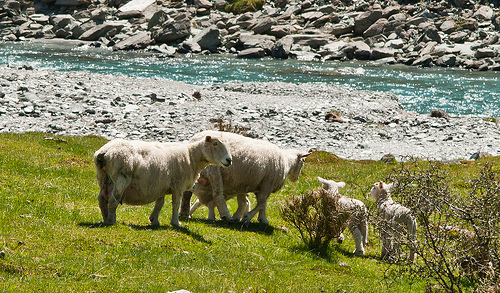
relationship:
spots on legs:
[118, 173, 132, 183] [108, 157, 131, 227]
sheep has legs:
[94, 132, 234, 230] [108, 157, 131, 227]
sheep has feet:
[94, 132, 234, 230] [93, 194, 183, 232]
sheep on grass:
[359, 175, 426, 269] [286, 174, 427, 284]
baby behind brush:
[361, 175, 428, 271] [370, 157, 499, 289]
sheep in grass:
[94, 132, 234, 230] [59, 128, 457, 291]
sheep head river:
[94, 132, 234, 230] [2, 43, 496, 155]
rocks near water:
[182, 21, 475, 78] [155, 32, 452, 92]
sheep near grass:
[165, 127, 314, 225] [111, 210, 331, 289]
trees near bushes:
[376, 160, 496, 289] [365, 172, 495, 263]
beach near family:
[82, 68, 317, 131] [122, 122, 408, 245]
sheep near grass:
[306, 173, 369, 265] [182, 215, 467, 291]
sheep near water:
[120, 134, 459, 277] [141, 43, 396, 95]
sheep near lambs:
[119, 123, 285, 190] [290, 172, 418, 248]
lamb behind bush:
[294, 178, 359, 228] [277, 180, 344, 270]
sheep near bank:
[94, 132, 234, 230] [67, 80, 357, 147]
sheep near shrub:
[306, 182, 446, 264] [279, 194, 371, 261]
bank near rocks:
[76, 82, 359, 162] [196, 9, 376, 49]